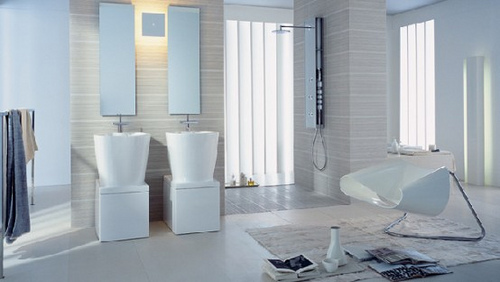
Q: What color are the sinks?
A: White.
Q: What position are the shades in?
A: Open.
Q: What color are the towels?
A: Blue and white.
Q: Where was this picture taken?
A: In a bathroom.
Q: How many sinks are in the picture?
A: Two.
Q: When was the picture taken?
A: During the day.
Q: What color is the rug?
A: Beige.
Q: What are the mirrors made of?
A: Glass.